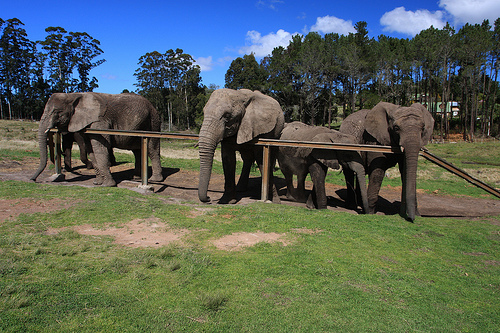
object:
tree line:
[225, 15, 491, 134]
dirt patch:
[211, 220, 322, 255]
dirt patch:
[45, 213, 210, 254]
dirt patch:
[0, 194, 98, 226]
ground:
[405, 152, 440, 201]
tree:
[132, 45, 203, 136]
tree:
[63, 28, 109, 98]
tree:
[222, 52, 254, 92]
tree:
[445, 19, 489, 134]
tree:
[297, 32, 331, 127]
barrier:
[47, 127, 500, 202]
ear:
[233, 88, 281, 144]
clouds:
[240, 26, 295, 59]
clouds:
[381, 6, 446, 37]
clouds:
[438, 0, 498, 23]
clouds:
[189, 56, 209, 70]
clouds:
[309, 13, 355, 35]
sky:
[2, 2, 498, 87]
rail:
[29, 123, 499, 211]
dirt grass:
[45, 217, 232, 259]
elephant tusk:
[44, 121, 59, 135]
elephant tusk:
[394, 140, 408, 155]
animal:
[336, 100, 439, 224]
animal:
[275, 117, 375, 212]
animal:
[190, 87, 285, 205]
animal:
[30, 92, 165, 189]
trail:
[5, 148, 498, 222]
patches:
[41, 196, 351, 300]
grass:
[20, 191, 400, 315]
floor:
[47, 177, 132, 311]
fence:
[38, 128, 500, 203]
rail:
[37, 125, 499, 202]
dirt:
[47, 212, 189, 247]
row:
[0, 17, 499, 138]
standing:
[212, 151, 243, 257]